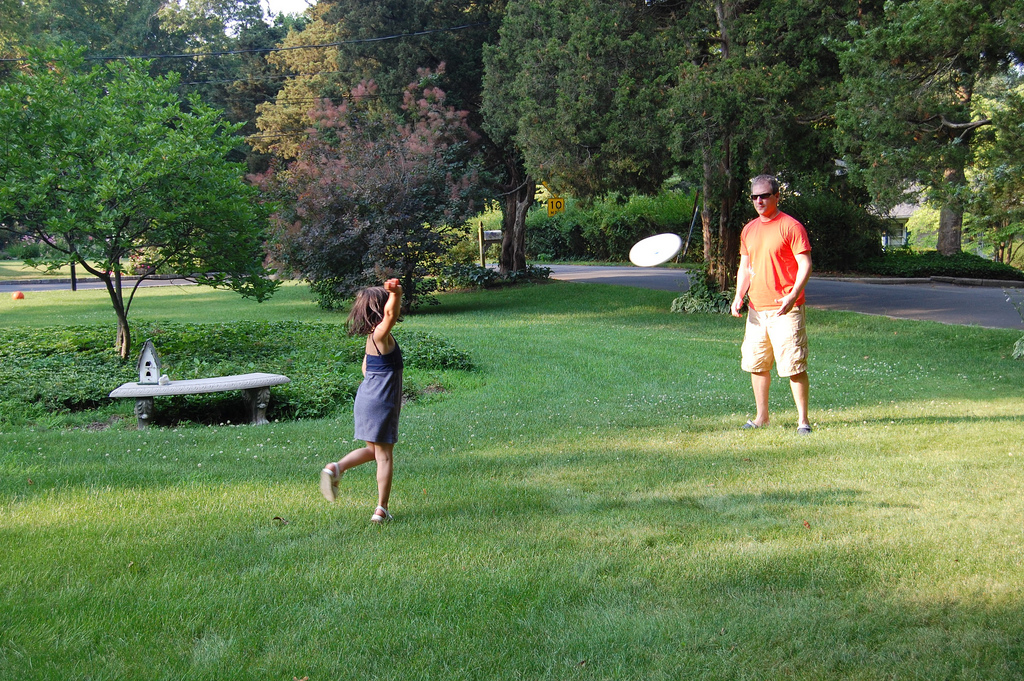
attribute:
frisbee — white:
[625, 229, 690, 267]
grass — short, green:
[0, 279, 1019, 678]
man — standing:
[724, 169, 819, 435]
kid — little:
[320, 276, 435, 521]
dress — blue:
[355, 330, 407, 448]